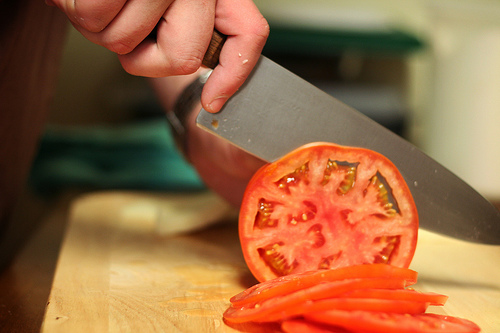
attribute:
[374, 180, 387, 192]
seed — showing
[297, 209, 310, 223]
seed — showing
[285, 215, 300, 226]
seed — showing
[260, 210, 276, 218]
seed — showing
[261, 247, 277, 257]
seed — showing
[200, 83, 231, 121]
fingernail — rough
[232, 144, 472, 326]
tomato — red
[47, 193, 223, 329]
board — wooden, cutting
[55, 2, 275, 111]
fingers — light-colored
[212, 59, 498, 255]
blade — large, silver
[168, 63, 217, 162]
band — black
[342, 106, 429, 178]
knife — metallic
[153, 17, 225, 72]
handle — wooden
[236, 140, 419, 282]
tomato — thin-sliced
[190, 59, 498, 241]
knife — metallic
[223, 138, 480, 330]
tomato — round, red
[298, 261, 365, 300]
slices — red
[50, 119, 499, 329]
cutting board — light-colored, wooden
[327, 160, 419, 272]
seeds — tomato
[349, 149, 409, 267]
flesh — tomato, red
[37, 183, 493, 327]
board — light brown , wood, wooden, brown